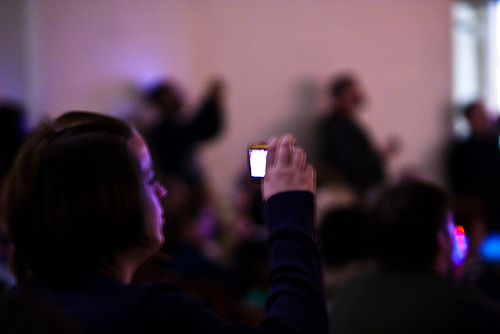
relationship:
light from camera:
[252, 153, 264, 174] [245, 145, 272, 180]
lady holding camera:
[1, 105, 326, 332] [245, 145, 272, 180]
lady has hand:
[1, 105, 326, 332] [262, 133, 318, 199]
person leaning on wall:
[314, 71, 393, 185] [8, 3, 452, 189]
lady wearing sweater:
[1, 105, 326, 332] [3, 188, 329, 334]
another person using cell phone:
[145, 71, 227, 189] [208, 68, 229, 95]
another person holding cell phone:
[145, 71, 227, 189] [208, 68, 229, 95]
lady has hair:
[1, 105, 326, 332] [0, 111, 139, 282]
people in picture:
[11, 66, 495, 320] [2, 2, 496, 333]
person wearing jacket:
[314, 71, 393, 185] [320, 112, 383, 180]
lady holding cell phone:
[1, 105, 326, 332] [245, 145, 272, 180]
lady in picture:
[1, 105, 326, 332] [2, 2, 496, 333]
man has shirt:
[323, 176, 497, 332] [331, 273, 496, 332]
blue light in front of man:
[480, 237, 500, 267] [323, 176, 497, 332]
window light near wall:
[450, 2, 497, 106] [8, 3, 452, 189]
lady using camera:
[1, 105, 326, 332] [245, 145, 272, 180]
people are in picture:
[11, 66, 495, 320] [2, 2, 496, 333]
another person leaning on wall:
[145, 71, 227, 189] [8, 3, 452, 189]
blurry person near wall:
[445, 100, 497, 192] [8, 3, 452, 189]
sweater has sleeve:
[3, 188, 329, 334] [252, 191, 331, 332]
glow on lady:
[141, 159, 169, 234] [1, 105, 326, 332]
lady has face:
[1, 105, 326, 332] [124, 130, 172, 257]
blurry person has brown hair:
[445, 100, 497, 192] [463, 98, 481, 120]